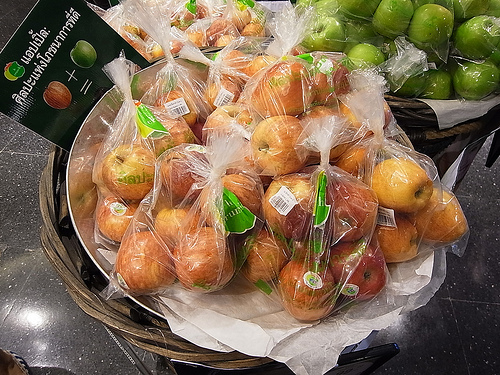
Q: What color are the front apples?
A: Red.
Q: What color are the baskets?
A: Brown.